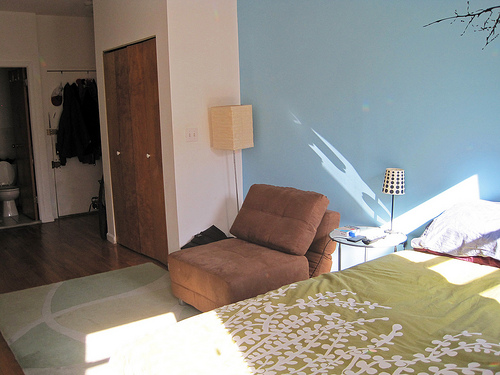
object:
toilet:
[0, 160, 20, 218]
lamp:
[207, 104, 255, 213]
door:
[101, 34, 167, 269]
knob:
[146, 154, 150, 159]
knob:
[116, 151, 120, 156]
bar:
[47, 69, 96, 75]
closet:
[40, 0, 106, 218]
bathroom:
[0, 65, 44, 229]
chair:
[168, 183, 341, 313]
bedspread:
[92, 248, 500, 375]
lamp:
[381, 167, 406, 234]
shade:
[381, 168, 406, 196]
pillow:
[411, 197, 500, 262]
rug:
[0, 261, 204, 375]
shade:
[207, 104, 254, 150]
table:
[328, 224, 407, 271]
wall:
[220, 4, 447, 106]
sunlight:
[330, 173, 498, 283]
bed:
[55, 196, 499, 374]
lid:
[0, 160, 15, 187]